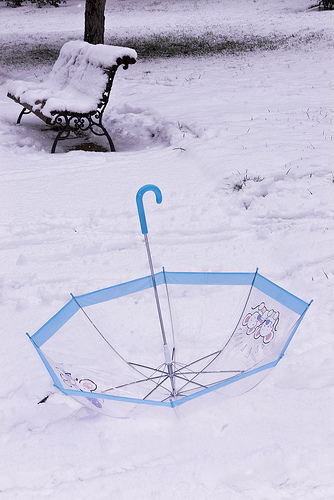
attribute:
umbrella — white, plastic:
[23, 174, 316, 447]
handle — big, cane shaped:
[134, 184, 164, 233]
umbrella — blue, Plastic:
[29, 210, 323, 412]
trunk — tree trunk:
[79, 6, 108, 31]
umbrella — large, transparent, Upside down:
[30, 240, 303, 418]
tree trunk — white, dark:
[80, 0, 106, 42]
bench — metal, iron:
[7, 40, 135, 151]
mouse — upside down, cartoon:
[241, 299, 266, 334]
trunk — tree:
[80, 24, 109, 45]